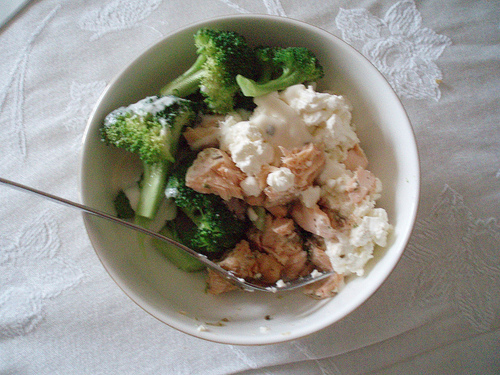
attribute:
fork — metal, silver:
[117, 200, 304, 309]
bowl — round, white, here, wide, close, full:
[349, 48, 424, 184]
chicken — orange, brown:
[191, 159, 241, 194]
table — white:
[392, 33, 492, 183]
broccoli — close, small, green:
[113, 101, 179, 187]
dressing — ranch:
[101, 97, 191, 124]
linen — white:
[2, 2, 484, 372]